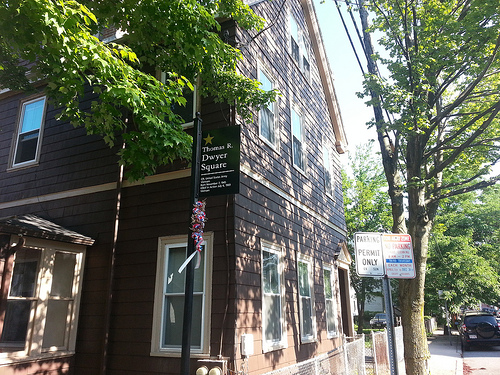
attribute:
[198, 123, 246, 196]
sign — black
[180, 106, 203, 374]
pole — metal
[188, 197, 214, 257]
flowers — hanging, tied, red, white, blue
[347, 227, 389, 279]
sign — parking sign, parking permit only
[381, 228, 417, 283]
sign — no parking sign, warning, red, white, blue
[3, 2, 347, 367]
house — three story, brown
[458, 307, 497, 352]
suv — parked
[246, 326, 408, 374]
fence — chain-link, chain link